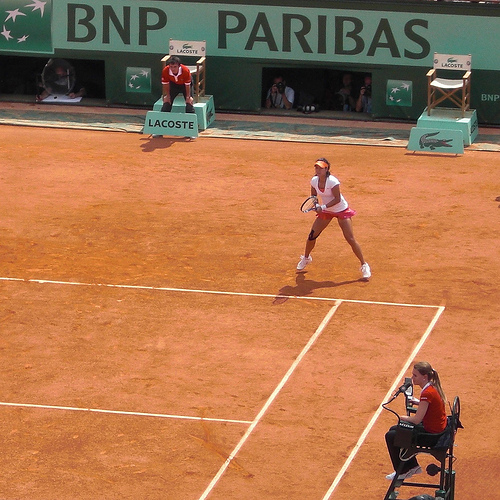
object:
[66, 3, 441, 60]
bnp paribas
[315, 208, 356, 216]
skirt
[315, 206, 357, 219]
shorts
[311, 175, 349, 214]
shirt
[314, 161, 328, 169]
visor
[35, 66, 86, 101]
man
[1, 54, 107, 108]
bunker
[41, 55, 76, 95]
tv camera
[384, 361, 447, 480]
woman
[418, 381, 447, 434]
shirt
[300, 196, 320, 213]
racket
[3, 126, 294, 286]
floor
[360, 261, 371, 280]
shoes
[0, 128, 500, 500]
court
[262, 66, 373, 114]
dugout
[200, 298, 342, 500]
sideline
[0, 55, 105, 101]
media dugout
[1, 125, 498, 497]
tennis court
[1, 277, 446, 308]
baseline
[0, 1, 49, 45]
logo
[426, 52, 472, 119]
chair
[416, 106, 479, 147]
block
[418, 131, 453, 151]
gator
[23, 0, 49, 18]
star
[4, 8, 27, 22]
star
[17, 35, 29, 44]
star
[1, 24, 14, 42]
star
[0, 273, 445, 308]
lines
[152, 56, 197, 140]
guy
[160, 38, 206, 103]
chair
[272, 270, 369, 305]
shadow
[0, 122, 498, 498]
ground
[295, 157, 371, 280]
tennis player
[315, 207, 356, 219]
pink skirt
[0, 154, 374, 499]
tennis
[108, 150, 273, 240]
red dirt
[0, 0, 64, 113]
corner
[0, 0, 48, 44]
circle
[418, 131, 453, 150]
image